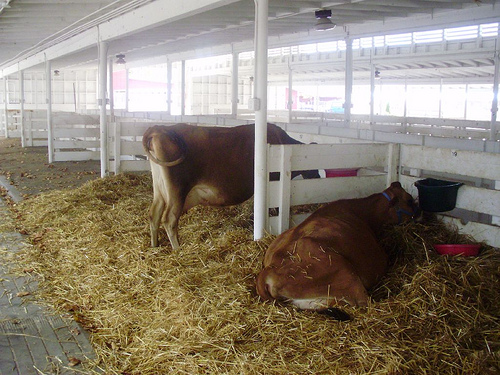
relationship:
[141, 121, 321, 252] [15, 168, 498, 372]
cow eats hay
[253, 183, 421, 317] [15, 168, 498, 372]
cow eats hay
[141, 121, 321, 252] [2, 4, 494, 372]
cow in barn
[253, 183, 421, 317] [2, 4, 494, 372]
cow in barn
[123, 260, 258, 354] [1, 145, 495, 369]
straw on ground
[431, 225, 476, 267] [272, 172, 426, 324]
pan in front cow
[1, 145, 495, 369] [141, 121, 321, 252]
ground behind cow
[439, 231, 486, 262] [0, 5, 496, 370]
red bowl in cow pen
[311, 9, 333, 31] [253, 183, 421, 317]
light fixtures hanging above cow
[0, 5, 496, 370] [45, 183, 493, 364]
cow pen covered in hay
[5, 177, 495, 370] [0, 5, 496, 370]
front part of cow pen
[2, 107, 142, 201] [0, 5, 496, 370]
back part of cow pen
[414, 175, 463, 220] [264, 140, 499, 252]
bucket hangs from fence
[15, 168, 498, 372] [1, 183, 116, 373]
hay on edge of a walkway